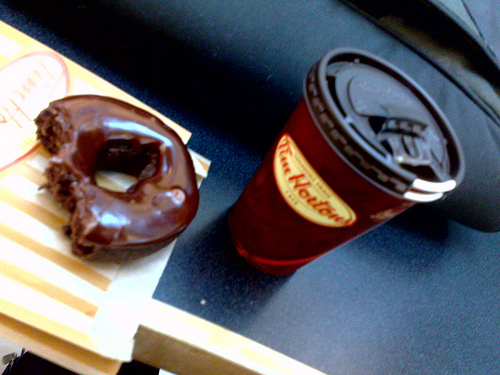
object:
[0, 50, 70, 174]
graphic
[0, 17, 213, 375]
bag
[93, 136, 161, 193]
hole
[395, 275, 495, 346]
floor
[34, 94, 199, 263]
cake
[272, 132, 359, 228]
label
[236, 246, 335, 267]
swirl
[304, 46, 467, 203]
lid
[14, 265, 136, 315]
papers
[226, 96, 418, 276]
coffee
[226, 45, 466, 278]
bottle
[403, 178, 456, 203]
part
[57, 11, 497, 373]
table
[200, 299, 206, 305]
spot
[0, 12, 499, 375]
stand